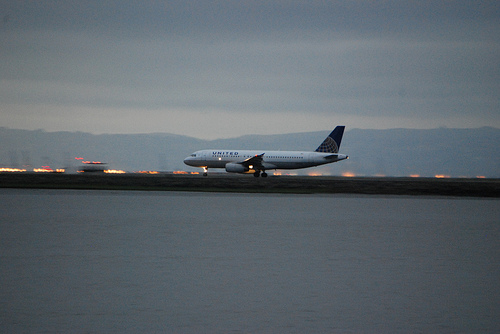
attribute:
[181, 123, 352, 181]
plane — united, white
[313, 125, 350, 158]
tail — blue, white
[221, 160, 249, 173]
jet engine — white, large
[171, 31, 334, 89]
sky — hazy